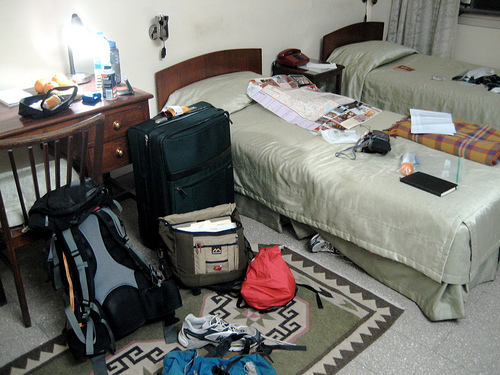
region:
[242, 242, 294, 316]
There is a red bag that is on the floor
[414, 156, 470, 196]
There is a black book that is on the bed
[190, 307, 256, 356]
There is a running shoe by New Balance on the rg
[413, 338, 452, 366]
There is tile that has a light beige hue to it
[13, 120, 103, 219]
There is a chair that is moved next to the desk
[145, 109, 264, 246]
There is a black bag that is near the bed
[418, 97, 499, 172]
There is a gold blanket that is on the bed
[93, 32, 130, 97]
There is a bottle of water on the desk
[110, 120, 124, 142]
There is a gold knob that is on the desk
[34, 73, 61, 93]
There are some oranges that are still on the desk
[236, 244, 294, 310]
A red drawstring bag on the floor.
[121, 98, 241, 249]
A black suitcase on the ground.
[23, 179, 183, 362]
A gray and black hiking pack leaning against a brown chair.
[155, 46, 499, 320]
A made bed next to a black suitcase.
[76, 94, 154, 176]
Two wooden drawers on a desk.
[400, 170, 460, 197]
A black journel on the bed.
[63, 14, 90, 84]
A gray lamp that is switched on.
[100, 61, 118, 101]
An empty bottle of Powerade on a desk.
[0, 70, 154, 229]
A brown desk with a lamp on it.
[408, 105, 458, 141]
A white stack of papers lying on a blanket on the bed.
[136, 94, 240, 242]
black suitcase beside bed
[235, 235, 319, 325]
red bag on floor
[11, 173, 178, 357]
backpack leaning against chair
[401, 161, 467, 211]
book laying on bed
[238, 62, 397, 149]
map laying open on bed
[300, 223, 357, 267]
athletic shoe under the bed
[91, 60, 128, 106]
shaving cream on desk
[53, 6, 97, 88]
lit lamp on desk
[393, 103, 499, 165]
folded blanket on bed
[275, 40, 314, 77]
red telephone on bed side table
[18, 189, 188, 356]
blue and black backpack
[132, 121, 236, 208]
dark green or dark blue suitcase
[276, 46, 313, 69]
red telephone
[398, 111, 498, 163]
tan plaid blanket throw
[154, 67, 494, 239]
twin bed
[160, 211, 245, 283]
gray travel bag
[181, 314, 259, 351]
one tennis shoe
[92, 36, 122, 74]
2 bottles of water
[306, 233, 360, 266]
part of a tennis shoe under the twin bed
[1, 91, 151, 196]
small brown wooden desk with wooden chair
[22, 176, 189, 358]
a backpack sitting on the rug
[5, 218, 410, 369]
a rug on the floor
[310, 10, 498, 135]
a bed next to the windo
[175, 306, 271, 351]
a tennis shoe on the rug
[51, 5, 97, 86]
a light on the desk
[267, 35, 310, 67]
a red phone on the nightstand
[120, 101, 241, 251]
a green suitcase next to the bed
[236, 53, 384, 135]
a map on the bed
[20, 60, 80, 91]
fruit on the desk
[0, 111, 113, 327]
a chair near the desk